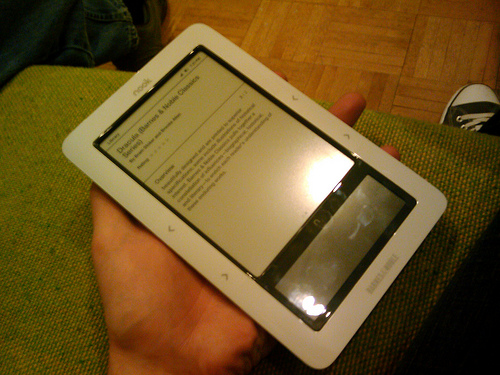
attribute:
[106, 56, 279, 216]
text — bunch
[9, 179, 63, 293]
pillow — throw, green, small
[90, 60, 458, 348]
reader — e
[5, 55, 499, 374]
cushion — green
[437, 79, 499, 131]
shoe — black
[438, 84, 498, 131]
sneaker — black, white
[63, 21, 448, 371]
e-reader — e, nook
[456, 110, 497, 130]
laces — white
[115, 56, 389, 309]
screen — device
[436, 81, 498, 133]
converse shoe — grey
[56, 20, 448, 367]
reader — e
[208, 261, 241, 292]
button — back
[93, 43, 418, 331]
screen — tablet, device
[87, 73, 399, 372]
hand — open